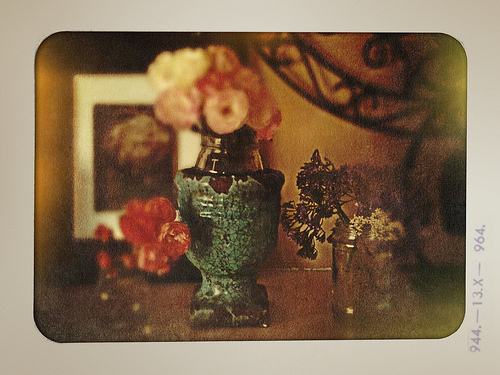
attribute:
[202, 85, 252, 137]
flower — pictured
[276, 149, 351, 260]
flower — pictured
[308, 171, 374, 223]
flower — pictured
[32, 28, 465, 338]
still life — beautiful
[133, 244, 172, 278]
flower — red, lovely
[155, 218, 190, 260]
flower — red, lovely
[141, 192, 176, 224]
flower — red, lovely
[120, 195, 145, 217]
flower — red, lovely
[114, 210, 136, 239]
flower — red, lovely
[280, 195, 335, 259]
flower — purple, pretty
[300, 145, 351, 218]
flower — purple, pretty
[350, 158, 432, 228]
flower — purple, pretty